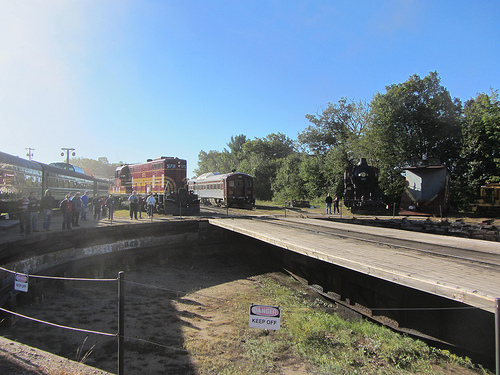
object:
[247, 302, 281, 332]
sign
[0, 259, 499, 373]
fence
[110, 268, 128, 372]
fence post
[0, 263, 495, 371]
wire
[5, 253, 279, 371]
shade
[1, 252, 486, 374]
ground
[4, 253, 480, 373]
grass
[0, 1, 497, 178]
sky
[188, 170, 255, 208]
train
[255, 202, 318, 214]
tracks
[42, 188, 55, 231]
person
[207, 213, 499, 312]
train tracks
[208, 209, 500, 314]
bridge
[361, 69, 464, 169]
leaves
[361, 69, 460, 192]
tree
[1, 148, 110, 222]
train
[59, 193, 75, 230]
people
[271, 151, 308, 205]
trees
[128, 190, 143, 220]
two people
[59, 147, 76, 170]
telephone pole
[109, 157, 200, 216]
train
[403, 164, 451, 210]
building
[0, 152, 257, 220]
several trains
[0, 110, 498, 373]
station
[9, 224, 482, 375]
area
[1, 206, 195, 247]
platform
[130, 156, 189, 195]
engine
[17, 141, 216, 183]
distance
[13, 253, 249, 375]
dirt